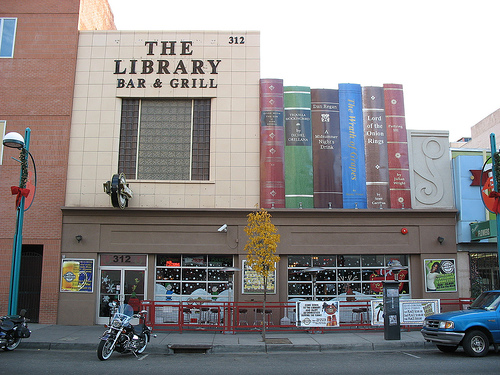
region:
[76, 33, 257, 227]
the library bar and grill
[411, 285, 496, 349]
blue pick up truck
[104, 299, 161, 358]
motorcycle on street side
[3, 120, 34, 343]
street light on blue pole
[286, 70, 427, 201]
store front that looks like books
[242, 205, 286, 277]
yellow leaves on small tree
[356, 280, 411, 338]
electronic parking meter machine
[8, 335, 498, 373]
paved road in foreground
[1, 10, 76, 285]
orange walls of store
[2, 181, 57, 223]
red ribbon on light post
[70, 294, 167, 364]
black motorcycle parked in front of the restaurant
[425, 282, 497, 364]
front of a blue vehicle parked on the street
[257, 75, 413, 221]
six large books painted on a sign on the building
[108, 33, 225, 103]
The Library Bar & Grill on the side of the building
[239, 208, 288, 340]
small thin tree with yellow leaves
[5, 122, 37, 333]
green street light with Christmas decorations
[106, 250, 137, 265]
number 312 above the door of the restaurant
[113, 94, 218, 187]
large block glass window on the building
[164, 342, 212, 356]
sewer opening drain on the curb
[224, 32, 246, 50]
number 312 near the top of the building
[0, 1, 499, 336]
a building wedged between two other buildings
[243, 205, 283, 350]
small tree with yellowing green leaves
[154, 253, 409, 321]
holiday scene portrayed in windows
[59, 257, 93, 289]
poster with a mug of beer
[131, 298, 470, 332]
black stools set at an outdoor counter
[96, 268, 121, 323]
snowflakes painted on glass door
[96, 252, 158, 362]
motorcycle parked near glass doors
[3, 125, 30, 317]
holiday decoration with a red bow around a street lamp pole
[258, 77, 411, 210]
large bound volumes depicted on building's facade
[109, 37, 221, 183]
large window made of frosted glass tiles below name of establishment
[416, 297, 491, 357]
the car is blue in color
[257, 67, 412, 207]
the model books are colored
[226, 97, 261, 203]
the roof has light brown tiles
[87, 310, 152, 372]
the motorbike is brown in color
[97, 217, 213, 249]
the wall is dark brown in color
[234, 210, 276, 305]
he plant has yellow leafs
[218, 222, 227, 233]
the light is white in color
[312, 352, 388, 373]
the pavement is grey in color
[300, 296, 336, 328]
words are written on a white board